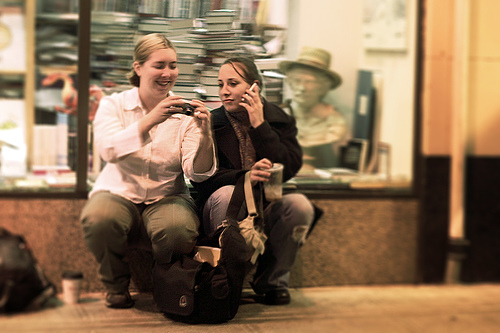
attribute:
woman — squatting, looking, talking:
[201, 57, 316, 303]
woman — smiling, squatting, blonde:
[81, 32, 217, 307]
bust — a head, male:
[280, 48, 346, 147]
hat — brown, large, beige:
[279, 47, 342, 89]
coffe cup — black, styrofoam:
[61, 270, 82, 303]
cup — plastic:
[261, 164, 284, 203]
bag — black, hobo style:
[160, 173, 249, 324]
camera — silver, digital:
[180, 102, 195, 116]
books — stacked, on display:
[201, 4, 249, 108]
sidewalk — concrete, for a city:
[1, 284, 499, 333]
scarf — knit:
[220, 108, 258, 171]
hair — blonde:
[124, 31, 178, 86]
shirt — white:
[92, 88, 218, 206]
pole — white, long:
[446, 2, 471, 284]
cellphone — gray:
[242, 84, 260, 103]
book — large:
[169, 20, 203, 29]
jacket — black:
[189, 98, 303, 202]